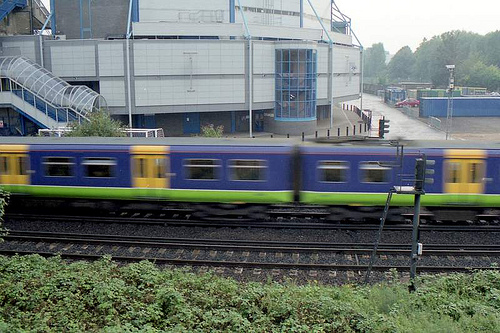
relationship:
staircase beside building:
[1, 54, 119, 133] [4, 3, 364, 137]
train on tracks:
[1, 134, 499, 209] [0, 205, 499, 280]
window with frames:
[277, 48, 317, 120] [275, 100, 322, 123]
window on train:
[183, 157, 221, 182] [1, 134, 499, 209]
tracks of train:
[0, 205, 499, 280] [1, 134, 499, 209]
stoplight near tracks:
[403, 152, 428, 208] [0, 205, 499, 280]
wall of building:
[133, 40, 248, 115] [4, 3, 364, 137]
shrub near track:
[2, 253, 497, 331] [2, 236, 499, 268]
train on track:
[1, 134, 499, 209] [4, 209, 499, 235]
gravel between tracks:
[2, 219, 490, 245] [0, 205, 499, 280]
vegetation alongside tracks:
[2, 253, 497, 331] [0, 205, 499, 280]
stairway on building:
[1, 54, 119, 133] [4, 3, 364, 137]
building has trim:
[4, 3, 364, 137] [107, 102, 258, 116]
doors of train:
[128, 152, 171, 195] [1, 134, 499, 209]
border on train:
[2, 186, 499, 212] [1, 134, 499, 209]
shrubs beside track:
[2, 253, 497, 331] [2, 236, 499, 268]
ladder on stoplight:
[356, 193, 401, 285] [413, 154, 435, 188]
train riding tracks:
[1, 134, 499, 209] [0, 205, 499, 280]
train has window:
[1, 134, 499, 209] [183, 157, 221, 182]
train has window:
[1, 134, 499, 209] [313, 160, 354, 186]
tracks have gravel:
[0, 205, 499, 280] [2, 219, 490, 245]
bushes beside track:
[2, 253, 497, 331] [2, 236, 499, 268]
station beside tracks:
[4, 3, 364, 137] [0, 205, 499, 280]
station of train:
[4, 3, 364, 137] [1, 134, 499, 209]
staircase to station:
[1, 54, 119, 133] [4, 3, 364, 137]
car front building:
[397, 94, 416, 110] [4, 3, 364, 137]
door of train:
[128, 152, 171, 195] [1, 134, 499, 209]